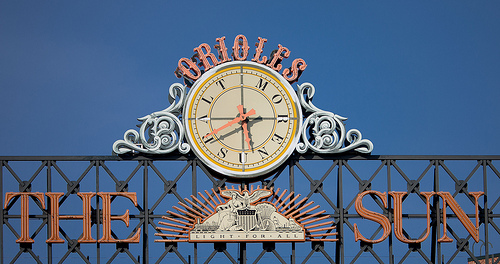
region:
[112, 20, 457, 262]
a clock on a fence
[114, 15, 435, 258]
a fence with a clock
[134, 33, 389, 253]
a metal clock on a fence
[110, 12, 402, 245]
a clock on a metal fence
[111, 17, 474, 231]
a metal clock on a metal fence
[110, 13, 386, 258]
an outside clock on the fence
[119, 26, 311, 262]
an outside clock on a metal fence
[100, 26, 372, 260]
an orioles clock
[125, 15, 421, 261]
an orioles metal clock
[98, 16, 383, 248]
an orioles clock on a fence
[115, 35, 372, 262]
baltimore based clock with Orioles on top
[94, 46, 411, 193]
baltimore sun clock with baltimore numbers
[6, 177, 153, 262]
the word on left is THE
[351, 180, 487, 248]
sun is written on the right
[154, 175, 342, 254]
light for all logo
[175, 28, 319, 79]
orange baltimore orioles name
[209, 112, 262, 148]
orange clock hands on clock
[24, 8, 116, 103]
blue sky on a beautiful day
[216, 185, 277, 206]
eagle on the top of logo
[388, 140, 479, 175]
metal sign holding the words The Sun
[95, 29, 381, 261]
A large clock on a metal scaffolding.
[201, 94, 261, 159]
neon red clock hands.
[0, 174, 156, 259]
a large the on a sign.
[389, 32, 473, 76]
a section of dark blue sky.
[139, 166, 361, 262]
a setting sun on a sign.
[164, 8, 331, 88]
writing on top of a clock.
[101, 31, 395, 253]
a large neon sign.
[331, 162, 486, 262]
A neon sun sign.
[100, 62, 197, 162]
a left white neon squiggle.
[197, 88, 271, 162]
two neon clock hands.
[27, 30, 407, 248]
this picture is taken outside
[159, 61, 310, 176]
this is a clock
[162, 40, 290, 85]
this sign says orioles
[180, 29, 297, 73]
the letters are orange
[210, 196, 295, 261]
this sign is white and orange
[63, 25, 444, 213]
the weather is clear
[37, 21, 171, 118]
the sky here is very blue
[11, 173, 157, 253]
this says "THE"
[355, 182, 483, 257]
this sign says "SUN"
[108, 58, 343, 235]
This sign is made of metal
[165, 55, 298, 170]
clock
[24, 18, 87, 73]
white clouds in blue sky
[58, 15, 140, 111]
white clouds in blue sky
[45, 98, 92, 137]
white clouds in blue sky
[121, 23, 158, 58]
white clouds in blue sky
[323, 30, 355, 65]
white clouds in blue sky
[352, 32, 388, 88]
white clouds in blue sky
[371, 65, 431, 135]
white clouds in blue sky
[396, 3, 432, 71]
white clouds in blue sky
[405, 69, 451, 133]
white clouds in blue sky